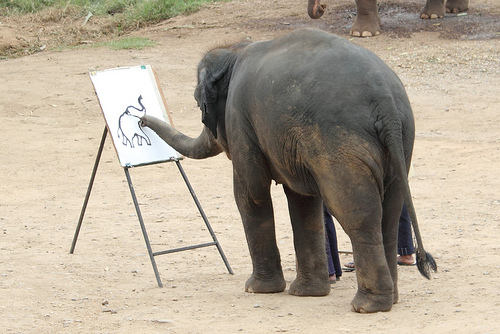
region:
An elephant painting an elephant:
[66, 24, 442, 318]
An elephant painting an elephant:
[56, 20, 441, 320]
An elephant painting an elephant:
[66, 23, 441, 314]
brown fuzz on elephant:
[188, 35, 254, 67]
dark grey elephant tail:
[349, 65, 467, 317]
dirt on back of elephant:
[279, 107, 419, 318]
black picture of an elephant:
[92, 53, 194, 182]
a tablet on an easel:
[68, 51, 233, 296]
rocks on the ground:
[392, 21, 482, 106]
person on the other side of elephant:
[288, 137, 446, 285]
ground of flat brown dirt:
[15, 7, 491, 328]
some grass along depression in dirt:
[0, 0, 185, 55]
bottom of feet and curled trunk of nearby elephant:
[300, 0, 470, 35]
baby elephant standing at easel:
[70, 25, 436, 312]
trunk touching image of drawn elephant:
[115, 90, 155, 150]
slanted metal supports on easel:
[65, 117, 232, 284]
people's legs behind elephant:
[291, 180, 426, 285]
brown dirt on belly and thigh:
[275, 107, 387, 219]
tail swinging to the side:
[350, 105, 442, 316]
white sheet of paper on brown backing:
[85, 56, 183, 166]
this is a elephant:
[105, 18, 436, 325]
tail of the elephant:
[363, 81, 486, 283]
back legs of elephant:
[305, 122, 404, 317]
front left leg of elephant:
[218, 150, 302, 322]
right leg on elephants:
[275, 174, 339, 296]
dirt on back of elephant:
[285, 107, 414, 323]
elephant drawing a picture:
[73, 34, 273, 296]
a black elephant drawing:
[85, 47, 178, 176]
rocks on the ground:
[408, 33, 492, 118]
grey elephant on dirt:
[140, 39, 439, 311]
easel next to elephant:
[69, 64, 236, 292]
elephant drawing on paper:
[115, 92, 148, 147]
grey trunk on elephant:
[139, 113, 217, 162]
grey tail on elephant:
[380, 112, 441, 286]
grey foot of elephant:
[349, 284, 396, 316]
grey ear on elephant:
[202, 65, 229, 114]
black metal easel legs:
[66, 123, 236, 284]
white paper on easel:
[89, 65, 181, 165]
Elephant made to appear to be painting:
[74, 58, 178, 223]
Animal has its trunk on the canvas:
[91, 25, 257, 208]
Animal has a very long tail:
[336, 65, 458, 313]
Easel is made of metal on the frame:
[32, 33, 245, 323]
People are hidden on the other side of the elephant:
[223, 58, 475, 320]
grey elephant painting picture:
[64, 24, 439, 319]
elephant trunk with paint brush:
[115, 94, 218, 165]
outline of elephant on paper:
[64, 60, 236, 282]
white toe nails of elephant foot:
[347, 14, 383, 41]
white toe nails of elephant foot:
[347, 19, 384, 40]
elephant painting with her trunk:
[137, 19, 442, 311]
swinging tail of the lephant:
[384, 137, 441, 284]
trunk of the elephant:
[140, 105, 205, 157]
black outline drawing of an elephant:
[102, 95, 160, 152]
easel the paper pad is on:
[64, 115, 231, 281]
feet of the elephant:
[243, 266, 399, 316]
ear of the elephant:
[190, 52, 229, 130]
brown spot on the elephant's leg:
[283, 115, 377, 217]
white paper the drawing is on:
[92, 56, 178, 165]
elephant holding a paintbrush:
[127, 104, 159, 135]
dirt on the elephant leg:
[288, 110, 391, 208]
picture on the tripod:
[51, 56, 241, 286]